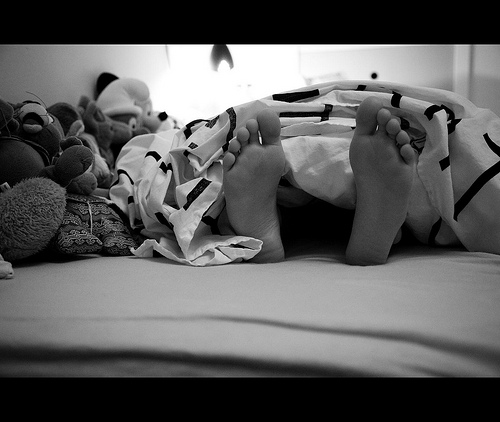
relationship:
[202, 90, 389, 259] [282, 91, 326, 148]
feet under blanket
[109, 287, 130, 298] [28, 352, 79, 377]
sheets on bed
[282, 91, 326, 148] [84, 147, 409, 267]
blanket on person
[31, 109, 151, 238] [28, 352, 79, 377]
animals on bed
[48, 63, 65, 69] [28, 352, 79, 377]
wall near bed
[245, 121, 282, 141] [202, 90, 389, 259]
toes on feet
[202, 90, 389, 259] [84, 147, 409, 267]
feet of person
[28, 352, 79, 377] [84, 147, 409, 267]
bed under person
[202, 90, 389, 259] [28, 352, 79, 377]
feet on bed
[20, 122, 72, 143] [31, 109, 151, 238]
face of animals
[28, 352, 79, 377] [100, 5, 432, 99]
bed in room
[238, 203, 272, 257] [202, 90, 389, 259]
heel of feet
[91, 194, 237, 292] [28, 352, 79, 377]
items on bed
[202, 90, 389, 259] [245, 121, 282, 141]
feet have toes